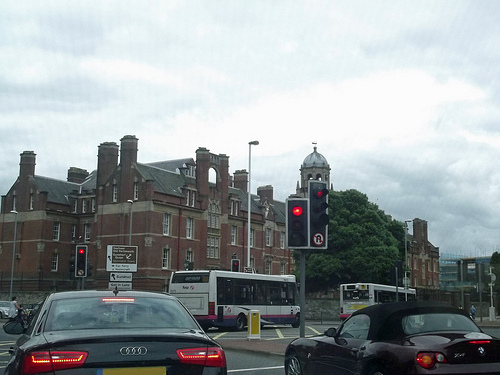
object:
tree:
[291, 189, 410, 282]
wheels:
[236, 316, 300, 331]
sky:
[0, 0, 500, 256]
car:
[285, 302, 500, 375]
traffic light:
[288, 200, 308, 247]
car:
[3, 286, 224, 375]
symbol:
[119, 346, 147, 355]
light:
[292, 206, 302, 216]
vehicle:
[340, 283, 417, 321]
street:
[0, 275, 500, 375]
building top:
[299, 141, 331, 170]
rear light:
[24, 351, 87, 372]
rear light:
[176, 347, 225, 367]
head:
[12, 296, 18, 300]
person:
[9, 296, 30, 328]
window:
[217, 278, 225, 305]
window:
[237, 279, 251, 305]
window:
[259, 280, 268, 305]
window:
[272, 282, 280, 304]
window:
[283, 282, 295, 305]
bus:
[168, 270, 300, 331]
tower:
[296, 143, 331, 198]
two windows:
[163, 214, 194, 239]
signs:
[106, 245, 137, 290]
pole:
[123, 306, 129, 322]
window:
[44, 297, 201, 332]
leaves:
[336, 213, 347, 225]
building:
[0, 135, 296, 291]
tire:
[234, 316, 244, 331]